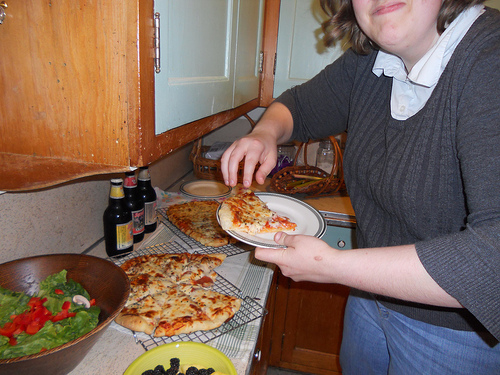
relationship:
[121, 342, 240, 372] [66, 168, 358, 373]
bowl on counter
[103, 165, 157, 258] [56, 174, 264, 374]
bottles on counter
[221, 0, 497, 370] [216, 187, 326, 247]
woman holding plate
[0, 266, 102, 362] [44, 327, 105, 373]
salad in bowl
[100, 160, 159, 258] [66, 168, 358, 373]
bottles in counter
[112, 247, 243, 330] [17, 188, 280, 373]
pizza on table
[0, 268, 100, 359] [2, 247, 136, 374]
salad in bowl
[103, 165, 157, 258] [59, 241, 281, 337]
bottles on table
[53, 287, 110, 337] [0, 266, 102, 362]
mushroom in salad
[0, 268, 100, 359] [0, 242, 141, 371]
salad in bowl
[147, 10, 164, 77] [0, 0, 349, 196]
hinge on cabinet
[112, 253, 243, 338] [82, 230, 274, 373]
pizza on top of tray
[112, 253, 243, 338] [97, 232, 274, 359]
pizza on top of tray